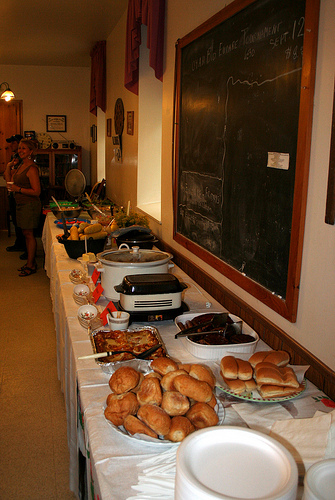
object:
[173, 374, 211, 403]
rolls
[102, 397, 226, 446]
plate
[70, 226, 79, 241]
corn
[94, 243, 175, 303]
crock pot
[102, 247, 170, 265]
lid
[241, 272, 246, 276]
chalk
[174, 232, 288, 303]
chalk holder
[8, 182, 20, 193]
hand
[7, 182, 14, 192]
cup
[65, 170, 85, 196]
fan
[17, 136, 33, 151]
hair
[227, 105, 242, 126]
part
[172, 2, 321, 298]
blackboard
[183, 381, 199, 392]
part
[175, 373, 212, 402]
bread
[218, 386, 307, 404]
edge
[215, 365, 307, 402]
plate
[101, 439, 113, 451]
part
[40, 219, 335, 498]
cloth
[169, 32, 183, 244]
edge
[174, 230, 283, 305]
edge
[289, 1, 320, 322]
edge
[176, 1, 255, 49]
edge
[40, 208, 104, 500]
edge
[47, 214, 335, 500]
table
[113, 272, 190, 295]
lid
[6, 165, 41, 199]
arm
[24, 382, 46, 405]
part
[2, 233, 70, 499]
floor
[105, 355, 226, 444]
dish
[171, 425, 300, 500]
dishes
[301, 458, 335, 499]
dishes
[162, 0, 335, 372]
wall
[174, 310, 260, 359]
container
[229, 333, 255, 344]
meat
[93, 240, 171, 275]
pot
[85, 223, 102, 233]
french bread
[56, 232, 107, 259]
bowl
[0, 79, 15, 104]
lamp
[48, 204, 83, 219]
bowl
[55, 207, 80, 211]
food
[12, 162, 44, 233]
dress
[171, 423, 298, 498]
plates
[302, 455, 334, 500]
plates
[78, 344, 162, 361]
serving spoon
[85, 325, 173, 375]
tray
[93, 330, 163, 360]
food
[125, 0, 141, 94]
curtains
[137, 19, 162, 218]
window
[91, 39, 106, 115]
curtains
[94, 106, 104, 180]
window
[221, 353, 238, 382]
rolls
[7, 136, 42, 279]
person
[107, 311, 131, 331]
cup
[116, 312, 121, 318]
food